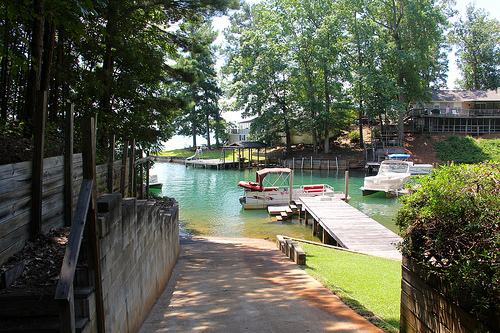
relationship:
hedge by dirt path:
[397, 138, 499, 308] [158, 227, 365, 331]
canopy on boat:
[250, 162, 297, 191] [234, 167, 350, 210]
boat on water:
[234, 167, 350, 210] [147, 159, 405, 247]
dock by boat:
[296, 192, 410, 262] [233, 164, 343, 211]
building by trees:
[395, 75, 495, 137] [253, 21, 461, 172]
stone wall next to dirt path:
[98, 190, 180, 331] [137, 234, 383, 331]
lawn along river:
[280, 234, 408, 326] [130, 153, 498, 240]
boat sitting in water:
[234, 167, 350, 210] [187, 169, 217, 206]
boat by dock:
[234, 167, 350, 210] [270, 174, 339, 222]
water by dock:
[187, 169, 217, 206] [270, 174, 339, 222]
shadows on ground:
[109, 212, 362, 329] [134, 229, 395, 331]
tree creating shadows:
[57, 2, 184, 219] [137, 237, 399, 332]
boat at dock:
[234, 167, 350, 210] [264, 168, 404, 260]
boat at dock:
[354, 151, 445, 196] [264, 168, 404, 260]